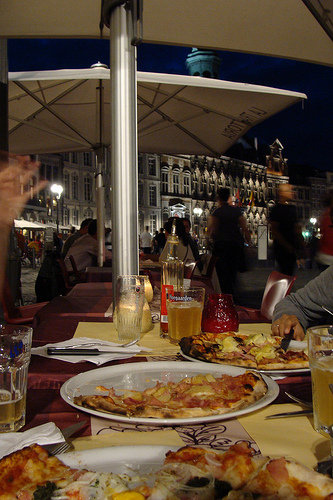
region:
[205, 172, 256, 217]
the head of a woman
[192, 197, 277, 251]
the arms on a woman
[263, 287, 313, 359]
the hand of a person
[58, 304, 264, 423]
pizza on a table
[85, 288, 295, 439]
a cheese pizza on a table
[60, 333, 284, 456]
a pizza with cheese on it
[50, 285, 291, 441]
a plate with pizza on it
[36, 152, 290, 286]
people in the background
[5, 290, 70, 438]
a glass on a table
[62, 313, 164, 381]
a knife on a table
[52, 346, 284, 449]
half of pizza on plate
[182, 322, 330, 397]
almost whole pizza on plate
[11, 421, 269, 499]
piece gone from pizza on plate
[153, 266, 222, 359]
glass of beer on table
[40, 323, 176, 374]
fork and knife on napkin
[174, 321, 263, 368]
burnt crust on pizza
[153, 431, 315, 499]
tomato sauce on pizza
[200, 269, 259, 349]
red candle holder on table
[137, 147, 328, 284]
people sitting and standing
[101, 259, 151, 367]
empty glass on table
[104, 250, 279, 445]
This is a restuarant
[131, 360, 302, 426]
This is delicious pizza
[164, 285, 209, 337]
This is a glass of beer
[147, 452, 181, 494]
These are yellow onions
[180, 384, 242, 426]
This is a thin crust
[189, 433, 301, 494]
The crust is white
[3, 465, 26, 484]
The sauce is red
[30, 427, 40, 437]
This is a napkin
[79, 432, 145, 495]
This is a plate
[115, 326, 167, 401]
The plate is white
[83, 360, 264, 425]
pizza on the plate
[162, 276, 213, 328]
beer in the glass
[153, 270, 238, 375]
beer in the glass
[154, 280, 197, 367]
beer in the glass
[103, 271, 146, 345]
A clear water glass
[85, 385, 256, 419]
Two to three pieces of pizzas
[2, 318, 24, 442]
A glass of beer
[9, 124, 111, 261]
An umbrella for outdoor seating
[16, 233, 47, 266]
A party of diners under an umbrella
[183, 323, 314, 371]
A full pizza without a single piece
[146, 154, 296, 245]
A line of building facing the eating area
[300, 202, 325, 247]
Some street lights are lit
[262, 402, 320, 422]
A knife is placed on the placemat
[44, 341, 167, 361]
A pizza knife is on a piece of paper napkin